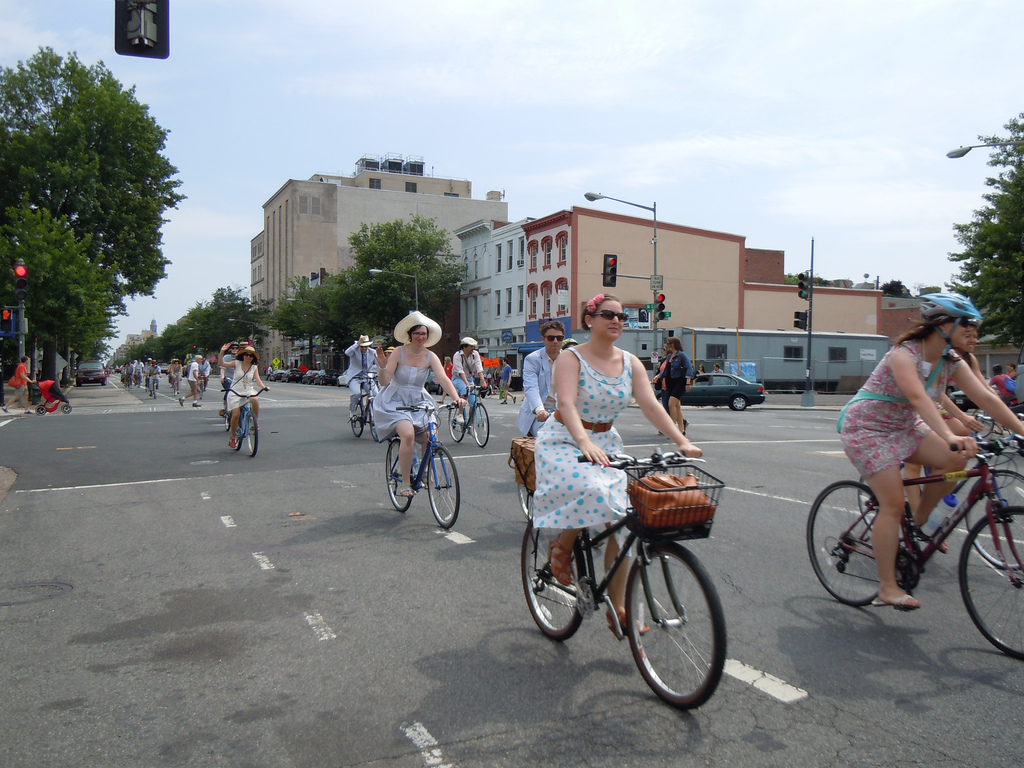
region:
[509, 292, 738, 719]
Woman riding bicycle with purse in basket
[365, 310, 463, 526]
Woman riding bicycle and waving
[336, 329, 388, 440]
Man wearing suit riding bicycle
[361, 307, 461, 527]
Woman in sundress riding a bicycle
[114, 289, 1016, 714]
Group of bicyclists wearing nice clothing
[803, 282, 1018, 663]
Woman wearing sundress and bicycle helmet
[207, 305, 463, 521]
Two women riding blue bicycles and waving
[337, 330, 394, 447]
Man holding hat while riding bicycle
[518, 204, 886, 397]
Peach and cream colored building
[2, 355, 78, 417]
Person pushing baby stroller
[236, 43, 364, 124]
white clouds in blue sky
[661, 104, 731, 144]
white clouds in blue sky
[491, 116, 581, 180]
white clouds in blue sky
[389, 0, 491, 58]
white clouds in blue sky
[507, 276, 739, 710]
woman riding bike in street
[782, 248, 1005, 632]
woman riding bike in street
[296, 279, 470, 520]
woman riding bike in street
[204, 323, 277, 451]
woman riding bike in street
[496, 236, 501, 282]
a window on a building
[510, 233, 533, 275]
a window on a building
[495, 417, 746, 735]
a two wheeled bicycle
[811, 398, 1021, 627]
a two wheeled bicycle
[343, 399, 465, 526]
a two wheeled bicycle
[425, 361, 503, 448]
a two wheeled bicycle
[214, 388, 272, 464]
a two wheeled bicycle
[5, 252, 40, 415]
A red light on a traffic signal.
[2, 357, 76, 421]
A person in an oragne top pushing and orange colored stroller into the street.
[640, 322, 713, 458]
Two women walking in a marked crosswalk.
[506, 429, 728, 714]
A black bicycle with baskets on the front and the back of the bicycle.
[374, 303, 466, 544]
Woman wearing a white hat riding a blue colored bicycle.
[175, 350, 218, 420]
A man walking across the street.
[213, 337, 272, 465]
A woman riding a bicycle with her right arm raised.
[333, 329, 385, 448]
A man wearing a suit while riding a bicycle.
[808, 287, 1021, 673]
A woman wearing a light blue bicycle helmet while bicycling.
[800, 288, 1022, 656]
a women in a pink floral dress and helmet riding a bike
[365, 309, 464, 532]
a women in a light dress and sun hat riding a bike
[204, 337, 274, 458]
a women in a white dress and sun dress riding a bike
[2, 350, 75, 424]
a person in a red shirt pushing a red stroller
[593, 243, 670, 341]
two red traffic lights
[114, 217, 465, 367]
a row of leafy green trees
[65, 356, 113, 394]
a maroon car driving down the street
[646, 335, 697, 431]
two people walking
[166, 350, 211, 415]
a man in a white shirt and hat walking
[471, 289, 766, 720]
woman wearing dress riding bike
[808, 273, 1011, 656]
woman wearing dress riding bike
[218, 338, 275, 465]
woman wearing dress riding bike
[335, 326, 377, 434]
man wearing suit riding bike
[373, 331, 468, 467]
woman in dress riding bike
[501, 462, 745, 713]
black metal bike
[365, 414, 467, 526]
blue metal bike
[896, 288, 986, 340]
light blue bike helmet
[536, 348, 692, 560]
white sundress with blue flowers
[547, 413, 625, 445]
brown leather belt on dress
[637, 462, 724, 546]
brown leather bag in basket on front of bike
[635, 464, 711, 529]
The brown purse in the basket of the bike.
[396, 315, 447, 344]
The cream colored hat on the woman's head.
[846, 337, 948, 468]
The pink pattern dress the woman is wearing.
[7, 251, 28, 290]
The red light on the traffic light above the woman pushing a stroller.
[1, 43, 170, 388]
The green tree on the left side of the street.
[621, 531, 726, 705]
The front wheel of the bicycle that has the purse in the basket.